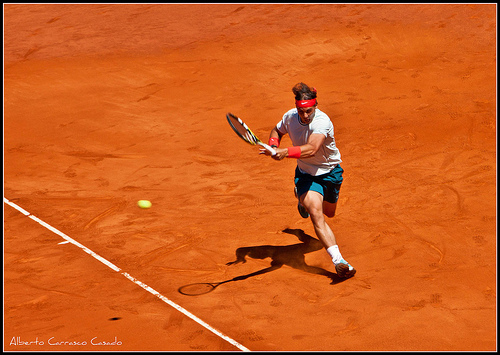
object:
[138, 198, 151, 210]
ball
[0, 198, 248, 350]
line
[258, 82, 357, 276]
player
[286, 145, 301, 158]
wrist band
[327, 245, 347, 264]
sock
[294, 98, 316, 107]
sweat band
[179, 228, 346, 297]
shadow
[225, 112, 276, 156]
racket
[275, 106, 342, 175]
t-shirt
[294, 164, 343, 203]
shorts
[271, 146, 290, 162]
hand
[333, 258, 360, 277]
foot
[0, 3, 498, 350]
court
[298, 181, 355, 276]
leg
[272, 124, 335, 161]
arm